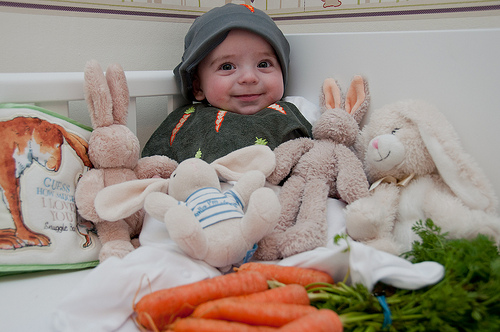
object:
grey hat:
[173, 1, 288, 106]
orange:
[243, 0, 258, 15]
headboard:
[1, 68, 183, 135]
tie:
[366, 286, 394, 331]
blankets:
[23, 238, 213, 330]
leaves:
[322, 296, 495, 328]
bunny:
[5, 115, 65, 243]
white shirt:
[178, 187, 246, 227]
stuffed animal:
[147, 149, 289, 261]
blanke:
[10, 86, 166, 292]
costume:
[172, 106, 307, 153]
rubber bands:
[375, 292, 394, 330]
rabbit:
[360, 103, 489, 258]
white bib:
[149, 97, 306, 179]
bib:
[0, 102, 107, 274]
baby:
[146, 0, 358, 189]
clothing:
[140, 101, 312, 152]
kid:
[141, 3, 311, 168]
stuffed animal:
[75, 55, 177, 262]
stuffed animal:
[252, 72, 369, 257]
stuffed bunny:
[346, 93, 498, 255]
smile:
[372, 150, 391, 164]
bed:
[0, 10, 492, 325]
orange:
[17, 119, 86, 244]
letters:
[38, 218, 74, 236]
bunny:
[95, 141, 279, 266]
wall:
[21, 15, 156, 62]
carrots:
[165, 105, 198, 145]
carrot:
[126, 262, 272, 329]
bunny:
[356, 104, 497, 246]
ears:
[315, 71, 345, 115]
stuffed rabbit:
[241, 75, 381, 262]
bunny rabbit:
[71, 59, 178, 264]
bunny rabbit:
[255, 73, 373, 262]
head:
[192, 27, 283, 114]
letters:
[37, 175, 70, 192]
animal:
[75, 57, 183, 266]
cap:
[173, 4, 291, 94]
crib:
[15, 70, 334, 205]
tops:
[332, 244, 500, 327]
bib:
[201, 108, 261, 151]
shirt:
[175, 183, 246, 223]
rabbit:
[276, 85, 387, 208]